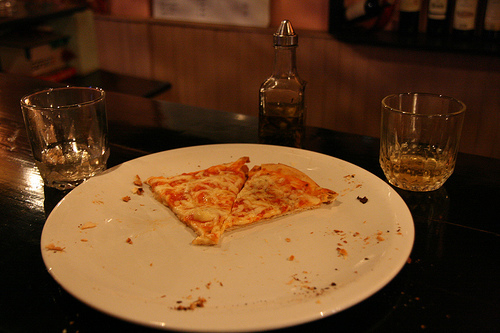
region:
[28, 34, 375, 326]
two slices of pizza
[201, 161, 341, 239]
slice of cheese pizza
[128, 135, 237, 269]
cheese pizza slice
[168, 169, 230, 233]
white and white topping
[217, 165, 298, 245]
white and red on pizaa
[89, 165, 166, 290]
crumbs on pizza plate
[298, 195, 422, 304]
white plate beneath pizza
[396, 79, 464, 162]
glass of liquid by plate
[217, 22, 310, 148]
glass of olive oil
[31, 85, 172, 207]
another glass of liquid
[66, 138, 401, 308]
a large white plate with leftover pizza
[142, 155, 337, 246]
two pieces of plain pizza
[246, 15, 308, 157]
a bottle of olive oil, set on the table top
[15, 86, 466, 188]
two identical glasses with different colored liquids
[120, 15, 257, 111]
wooden slat wainscoting on the room's wall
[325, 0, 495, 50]
a rack of wines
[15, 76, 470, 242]
two slices and two glasses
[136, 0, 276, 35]
menu board on the wall of the restaurant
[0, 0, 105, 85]
shelves holding various items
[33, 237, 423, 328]
half a plate, with crumbs of eaten food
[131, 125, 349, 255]
two slices of pizza on a plate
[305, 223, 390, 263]
crumbs on the plate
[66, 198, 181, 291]
plate is white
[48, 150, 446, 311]
plate is round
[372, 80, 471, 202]
empty glass on table to right of plate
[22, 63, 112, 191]
empty glass on table to left of plate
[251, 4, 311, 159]
bottle of olive oil with pouring spout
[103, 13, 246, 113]
wood type paneling in the background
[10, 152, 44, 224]
plate on shiny wooden table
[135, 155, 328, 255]
pizza with cheese topping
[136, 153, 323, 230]
pizza on plate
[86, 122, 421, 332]
plate is white and round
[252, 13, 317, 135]
oil dispenser behind plate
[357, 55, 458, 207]
scotch glass near plate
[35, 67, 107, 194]
empty glass near plate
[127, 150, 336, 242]
pizza is small and thin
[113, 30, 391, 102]
wall is brown and wood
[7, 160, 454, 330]
table is brown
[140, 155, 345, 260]
pizza is yellow and orange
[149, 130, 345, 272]
pizza has thin crust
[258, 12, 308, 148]
Bottle of olive oil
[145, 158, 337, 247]
2 pieces of pizza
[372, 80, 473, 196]
Glass filled 1/4 of the way with liquid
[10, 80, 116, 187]
Glass on left side of plate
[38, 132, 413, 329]
White plate holding pizza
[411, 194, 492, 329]
Portion of wood table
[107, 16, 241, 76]
Wood paneling in the background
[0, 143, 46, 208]
Glare from overhead lights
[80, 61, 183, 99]
Chair or bench in the background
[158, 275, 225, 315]
Crumbs on the plate